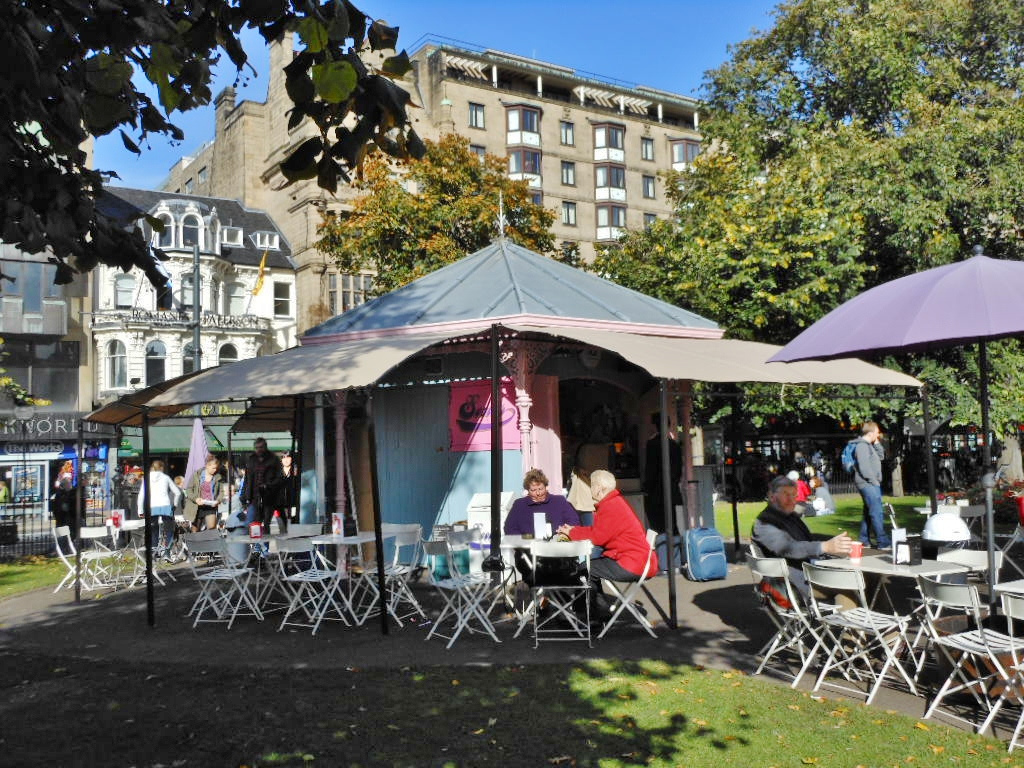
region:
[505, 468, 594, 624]
Person wearing purple jacket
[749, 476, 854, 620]
Man sitting at outdoor table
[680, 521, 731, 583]
Blue backpack leaning against wall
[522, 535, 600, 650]
White folding chair at outdoor table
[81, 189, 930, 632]
Outdoor cafe building with awnings on poles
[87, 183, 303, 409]
White town house with arched windows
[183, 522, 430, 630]
Empty white table and chairs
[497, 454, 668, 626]
two people sitting at the table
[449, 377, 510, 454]
advertisment sign on the tent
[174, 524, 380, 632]
chairs under the tent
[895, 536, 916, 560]
napkins on the table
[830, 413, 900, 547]
man wearing a backpack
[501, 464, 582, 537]
woman wearing a purple shirt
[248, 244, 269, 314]
yellow flag hanging off the building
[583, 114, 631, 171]
window on the building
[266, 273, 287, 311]
glass window on building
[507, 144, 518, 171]
glass window on building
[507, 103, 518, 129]
glass window on building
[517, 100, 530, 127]
glass window on building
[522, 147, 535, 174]
glass window on building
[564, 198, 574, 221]
glass window on building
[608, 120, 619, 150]
glass window on building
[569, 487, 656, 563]
woman wearing a red shirt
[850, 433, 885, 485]
man wearing a gray jacket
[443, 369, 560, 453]
pink sign on the wall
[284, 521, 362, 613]
white chair in front of the table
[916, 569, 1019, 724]
white chair in front of the table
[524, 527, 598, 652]
white chair in front of the table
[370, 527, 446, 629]
white chair in front of the table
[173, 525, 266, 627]
white chair in front of the table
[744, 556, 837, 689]
A chair is standing on the ground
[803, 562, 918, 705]
A chair is standing on the ground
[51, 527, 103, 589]
A chair is standing on the ground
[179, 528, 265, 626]
A chair is standing on the ground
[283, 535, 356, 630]
A chair is standing on the ground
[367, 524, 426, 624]
A chair is standing on the ground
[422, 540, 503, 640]
A chair is standing on the ground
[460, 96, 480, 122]
glass window on the building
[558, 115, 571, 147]
glass window on the building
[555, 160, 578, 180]
glass window on the building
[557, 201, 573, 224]
glass window on the building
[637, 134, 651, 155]
glass window on the building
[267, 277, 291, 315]
glass window on the building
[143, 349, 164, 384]
glass window on the building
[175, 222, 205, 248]
glass window on the building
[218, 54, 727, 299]
a large brown building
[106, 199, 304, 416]
a large white house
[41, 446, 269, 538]
people walking on the sidewalk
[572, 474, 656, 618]
a person in a red sweater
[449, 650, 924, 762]
grass in front of the chairs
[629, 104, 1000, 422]
a large tree behind the umbrella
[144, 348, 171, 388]
a window on the house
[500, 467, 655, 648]
two people eating outside a booth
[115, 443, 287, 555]
a small crowd milling about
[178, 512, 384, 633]
a group of white folding chairs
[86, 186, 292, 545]
a building that used to be a house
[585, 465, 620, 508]
gray hair shining in the sun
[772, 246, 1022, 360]
a large umbrella for shade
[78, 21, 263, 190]
sky peeking through the leaves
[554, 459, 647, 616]
man wearing red jacket